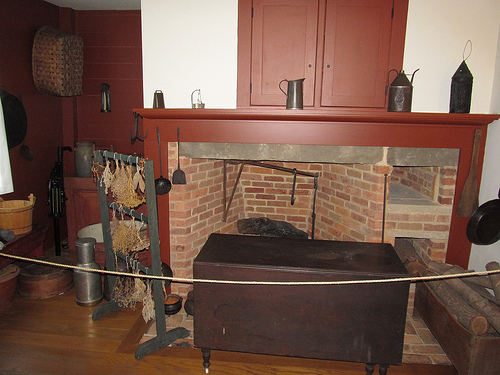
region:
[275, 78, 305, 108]
metal container on the fireplace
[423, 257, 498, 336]
wooden logs for the fire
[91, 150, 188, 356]
the rack has dried spices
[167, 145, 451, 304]
the fireplace is lined with red brick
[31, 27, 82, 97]
a wicker basket on the wall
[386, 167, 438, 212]
a hole for wood storage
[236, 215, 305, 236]
a blackened log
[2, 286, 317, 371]
hardwood floors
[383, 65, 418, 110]
a metal oil jar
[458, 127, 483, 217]
a wooden paddle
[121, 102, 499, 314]
wooden fireplace surround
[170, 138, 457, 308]
brick built fireplace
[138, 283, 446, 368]
bricks on a fireplace hearth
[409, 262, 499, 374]
a box of logs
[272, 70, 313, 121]
pewter jug on a fireplace shelf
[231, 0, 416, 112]
brown wooden cabinet doors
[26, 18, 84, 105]
a woven basket hangs on a wall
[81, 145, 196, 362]
seaweed is hanging on a stand to dry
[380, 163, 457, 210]
fireplace has a hole in the side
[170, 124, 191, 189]
a coal shovel hangs on a fireplace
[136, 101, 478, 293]
A fireplace.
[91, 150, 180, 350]
A drying rack for herbs.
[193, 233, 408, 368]
A storage box.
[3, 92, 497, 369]
A display.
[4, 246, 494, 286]
The rope to section off the display.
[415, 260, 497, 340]
The wood for the fireplace.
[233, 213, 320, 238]
Logs inside the fireplace.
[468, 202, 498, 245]
Frying pan hanging on the fireplace.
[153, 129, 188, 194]
Cooking utensils on the fireplace.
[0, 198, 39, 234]
A wooden pail.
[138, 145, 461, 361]
brick on the fireplace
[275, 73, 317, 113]
black pot on the mantle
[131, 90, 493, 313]
mantle is made of brown wood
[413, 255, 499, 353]
a pile of firewood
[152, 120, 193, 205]
tools hanging from the fireplace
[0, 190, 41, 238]
light brown basket on the floor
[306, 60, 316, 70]
small black dot on the cabinet door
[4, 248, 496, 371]
light brown wood on the floor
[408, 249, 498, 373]
firewood in a container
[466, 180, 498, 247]
black pan hanging up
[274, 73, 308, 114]
metal pitcher sitting on the mantle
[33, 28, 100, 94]
woven basket hanging on the wall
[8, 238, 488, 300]
rope closing off the exhibit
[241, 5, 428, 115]
cabinets above the fireplace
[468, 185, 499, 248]
frying pan hanging by the fireplace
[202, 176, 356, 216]
brick fireplace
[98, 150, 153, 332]
drying rack near the fireplace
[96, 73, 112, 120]
lantern on the wall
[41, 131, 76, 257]
water pump handle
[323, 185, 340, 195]
A brick in a wall.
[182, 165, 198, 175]
a brick in a wall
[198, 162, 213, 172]
a brick in a wall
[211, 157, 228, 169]
a brick in a wall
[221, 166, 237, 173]
a brick in a wall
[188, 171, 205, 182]
a brick in a wall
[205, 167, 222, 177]
a brick in a wall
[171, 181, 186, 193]
a brick in a wall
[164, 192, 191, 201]
a brick in a wall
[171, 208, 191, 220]
a brick in a wall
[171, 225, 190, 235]
a brick in a wall